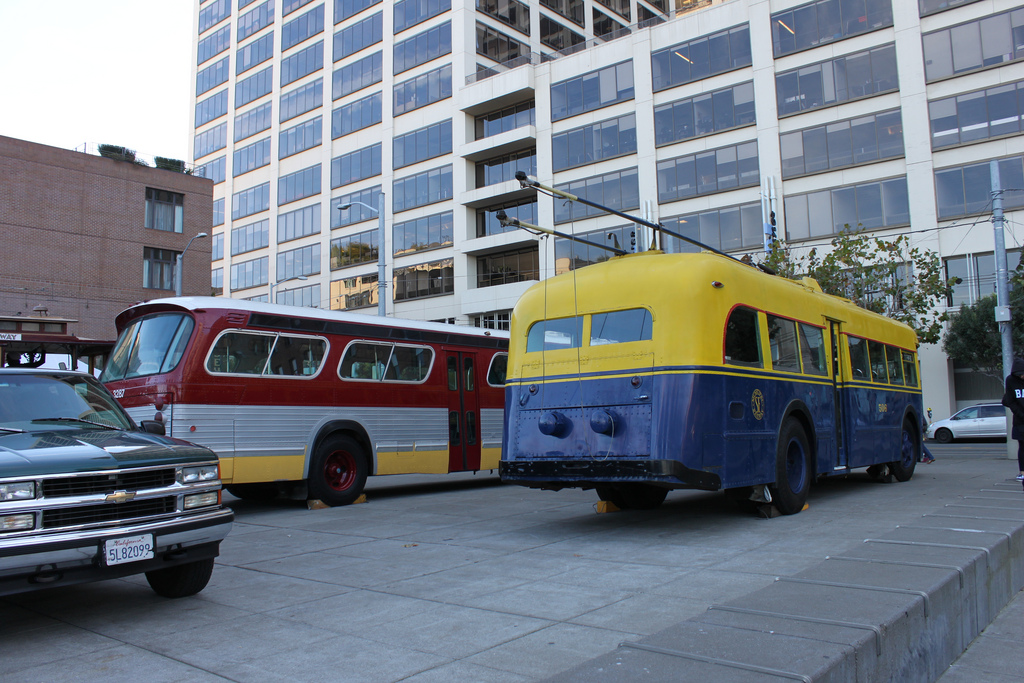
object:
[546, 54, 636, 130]
window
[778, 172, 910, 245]
window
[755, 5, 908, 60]
window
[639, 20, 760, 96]
window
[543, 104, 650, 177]
window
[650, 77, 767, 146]
window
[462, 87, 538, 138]
window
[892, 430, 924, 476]
tire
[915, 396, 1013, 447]
van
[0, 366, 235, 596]
suv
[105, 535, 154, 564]
license plate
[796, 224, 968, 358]
tree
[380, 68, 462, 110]
window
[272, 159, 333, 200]
window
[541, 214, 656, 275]
window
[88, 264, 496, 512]
bus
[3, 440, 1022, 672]
concrete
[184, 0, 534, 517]
building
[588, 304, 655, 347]
window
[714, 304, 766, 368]
window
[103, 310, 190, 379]
window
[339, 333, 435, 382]
window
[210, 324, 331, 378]
window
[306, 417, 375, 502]
tire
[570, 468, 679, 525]
tire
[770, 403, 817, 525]
tire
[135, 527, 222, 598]
tire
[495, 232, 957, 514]
bus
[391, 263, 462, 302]
window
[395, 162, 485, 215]
window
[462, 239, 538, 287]
window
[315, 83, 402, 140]
window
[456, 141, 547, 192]
window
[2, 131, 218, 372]
building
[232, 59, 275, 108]
window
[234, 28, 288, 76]
window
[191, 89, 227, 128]
window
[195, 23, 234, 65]
window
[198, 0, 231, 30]
window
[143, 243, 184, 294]
window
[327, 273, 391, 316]
window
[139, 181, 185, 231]
window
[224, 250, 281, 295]
window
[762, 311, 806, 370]
window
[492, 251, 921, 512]
bus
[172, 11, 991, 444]
building